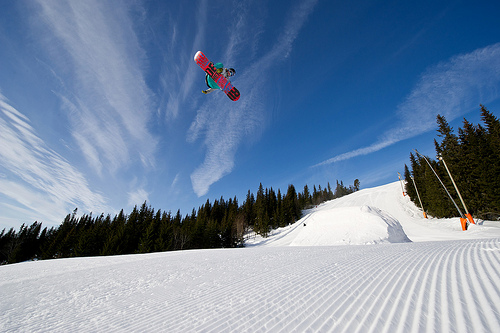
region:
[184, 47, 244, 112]
man doing tricks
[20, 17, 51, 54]
white clouds in blue sky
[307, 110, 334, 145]
white clouds in blue sky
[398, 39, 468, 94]
white clouds in blue sky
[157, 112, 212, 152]
white clouds in blue sky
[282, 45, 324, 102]
white clouds in blue sky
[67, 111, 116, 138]
white clouds in blue sky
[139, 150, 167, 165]
white clouds in blue sky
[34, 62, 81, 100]
white clouds in blue sky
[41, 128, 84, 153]
white clouds in blue sky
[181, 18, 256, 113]
snow board in air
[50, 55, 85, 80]
white clouds in blue sky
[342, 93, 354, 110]
white clouds in blue sky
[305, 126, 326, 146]
white clouds in blue sky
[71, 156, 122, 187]
white clouds in blue sky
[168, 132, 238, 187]
white clouds in blue sky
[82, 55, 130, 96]
white clouds in blue sky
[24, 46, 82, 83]
white clouds in blue sky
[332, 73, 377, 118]
white clouds in blue sky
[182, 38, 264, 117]
snow boarder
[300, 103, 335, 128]
white clouds in blue sky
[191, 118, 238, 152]
white clouds in blue sky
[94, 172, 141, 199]
white clouds in blue sky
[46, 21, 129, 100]
white clouds in blue sky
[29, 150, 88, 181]
white clouds in blue sky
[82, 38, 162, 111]
white clouds in blue sky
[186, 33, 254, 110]
the snowboarder in the air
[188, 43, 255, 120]
the person does a trick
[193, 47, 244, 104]
the bottom of the snowboard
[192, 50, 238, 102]
the letters on the base of the board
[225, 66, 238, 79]
the googles on the persons face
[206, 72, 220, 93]
the green pants of the snowboarder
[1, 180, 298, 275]
the green trees on theside of the mountain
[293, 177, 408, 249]
the snow piles for the ramp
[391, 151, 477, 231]
the flags on the side of the mountain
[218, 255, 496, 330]
the lines in the snow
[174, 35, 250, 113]
man on snow board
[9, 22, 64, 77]
white clouds in blue sky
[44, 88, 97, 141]
white clouds in blue sky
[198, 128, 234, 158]
white clouds in blue sky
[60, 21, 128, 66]
white clouds in blue sky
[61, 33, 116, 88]
white clouds in blue sky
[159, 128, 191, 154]
white clouds in blue sky